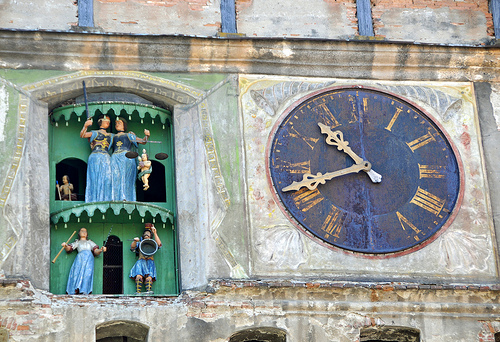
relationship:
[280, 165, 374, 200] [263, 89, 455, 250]
hand on top of clock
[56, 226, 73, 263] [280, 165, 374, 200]
stick in hand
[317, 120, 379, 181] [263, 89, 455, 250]
pointer attached to clock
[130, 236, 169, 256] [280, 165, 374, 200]
shield in hand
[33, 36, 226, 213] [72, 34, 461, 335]
scene on side of building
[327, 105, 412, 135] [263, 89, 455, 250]
numerals on front of clock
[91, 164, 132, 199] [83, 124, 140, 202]
people wearing robes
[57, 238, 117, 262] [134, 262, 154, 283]
person wearing robe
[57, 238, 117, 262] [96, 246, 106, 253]
person holding drum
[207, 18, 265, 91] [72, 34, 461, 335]
paint on side of building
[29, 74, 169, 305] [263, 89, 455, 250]
figurines next to clock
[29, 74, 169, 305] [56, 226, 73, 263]
figurines holding stick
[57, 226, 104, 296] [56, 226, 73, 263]
person holding stick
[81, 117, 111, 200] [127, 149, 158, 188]
people holding up puppet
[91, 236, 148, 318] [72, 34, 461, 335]
windows on building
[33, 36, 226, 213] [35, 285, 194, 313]
scene on display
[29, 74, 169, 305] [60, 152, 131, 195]
figurines wearing blue